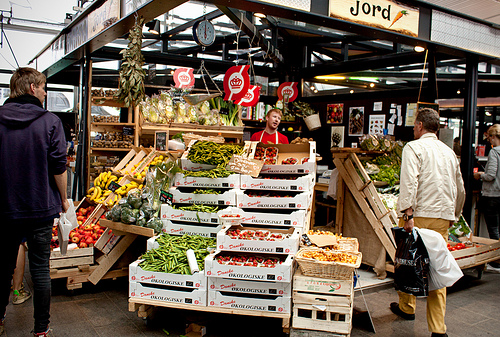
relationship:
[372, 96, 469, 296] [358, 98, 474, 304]
head of man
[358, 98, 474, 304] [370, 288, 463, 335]
man with shoe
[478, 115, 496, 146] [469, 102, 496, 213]
head of woman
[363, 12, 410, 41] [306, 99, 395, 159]
picture on wall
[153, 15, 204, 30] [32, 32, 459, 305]
light in shop